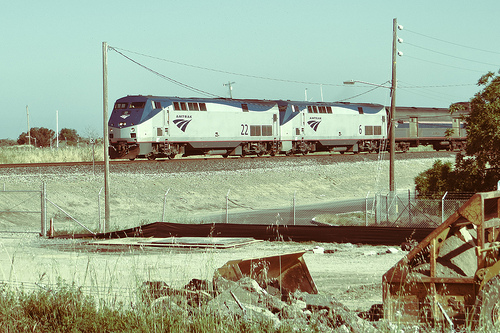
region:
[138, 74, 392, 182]
A train is visible.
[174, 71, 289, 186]
A train is visible.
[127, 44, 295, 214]
A train is visible.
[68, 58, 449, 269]
A train is visible.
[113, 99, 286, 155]
front of a train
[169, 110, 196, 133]
train logo on side of the train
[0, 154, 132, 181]
steel train tracks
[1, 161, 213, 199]
lots of rocks on the side of the train tracks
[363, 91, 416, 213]
power line pole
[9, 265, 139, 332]
small little desert shrubs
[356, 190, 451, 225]
chain link fence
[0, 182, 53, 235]
chain link closed gate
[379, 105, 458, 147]
train car compartment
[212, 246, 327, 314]
old front end of a bulldozer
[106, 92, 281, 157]
a blue and white train engine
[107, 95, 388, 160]
two blue and white train engines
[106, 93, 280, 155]
train engine number 22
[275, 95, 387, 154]
train engine number 6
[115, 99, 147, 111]
windshield of a train engine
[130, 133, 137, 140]
left headlight of a train engine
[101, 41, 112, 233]
wooden power pole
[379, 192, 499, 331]
a rusty metal bin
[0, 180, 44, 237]
a metal fence gate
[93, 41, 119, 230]
the pole is wooden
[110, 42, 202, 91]
the wires are connected to the pole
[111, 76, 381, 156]
the train is blue and white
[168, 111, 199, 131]
the train has a logo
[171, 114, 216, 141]
the logo is blue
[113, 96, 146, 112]
the train has a windshield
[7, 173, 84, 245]
the fence is high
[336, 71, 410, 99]
the street lamp is off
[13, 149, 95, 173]
the tracks are metal and brown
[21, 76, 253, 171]
a train on the tracks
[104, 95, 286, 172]
Large train moving on the tracks.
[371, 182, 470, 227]
Barbed wire fence near train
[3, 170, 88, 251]
Gated fence near the train tracks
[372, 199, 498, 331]
Rusty dumpster on dirt road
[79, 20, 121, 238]
Pole with electrical wires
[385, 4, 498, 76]
Electrical wires with blue sky in background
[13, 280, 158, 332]
Overgrown grass near dirt road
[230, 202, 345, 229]
Paved road with sharp curve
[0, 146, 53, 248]
Gate with barb wire near train tracks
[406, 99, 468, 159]
Silver train with blue and white stipes